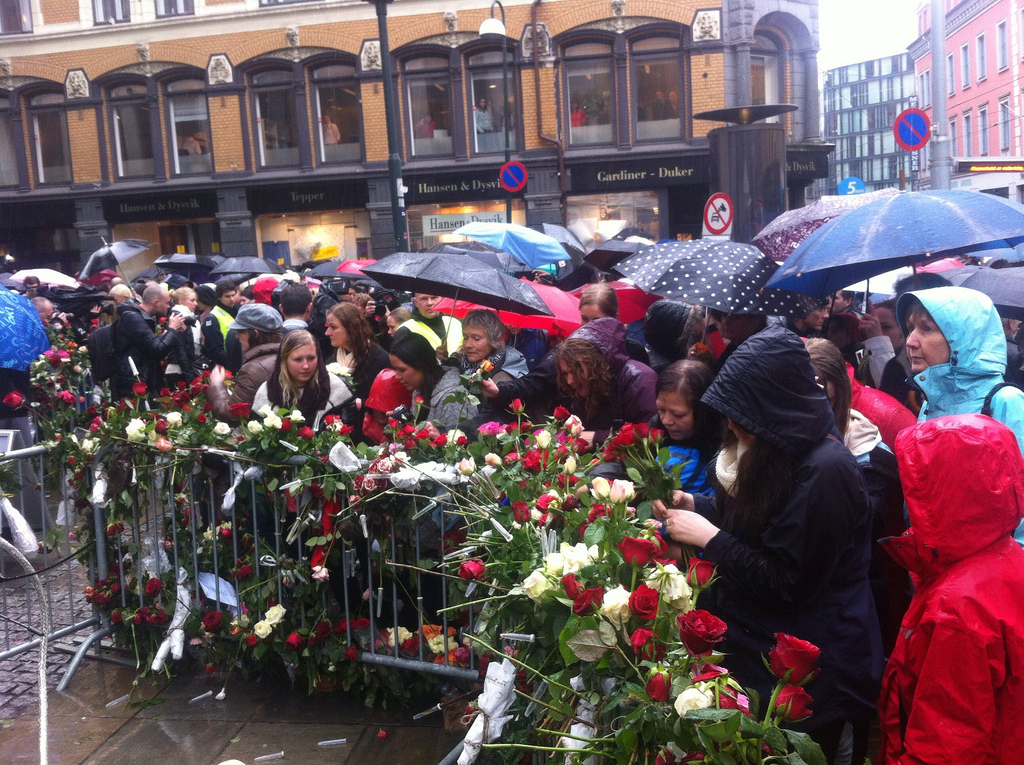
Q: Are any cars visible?
A: No, there are no cars.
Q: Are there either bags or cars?
A: No, there are no cars or bags.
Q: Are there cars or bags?
A: No, there are no cars or bags.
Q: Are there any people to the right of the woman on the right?
A: Yes, there is a person to the right of the woman.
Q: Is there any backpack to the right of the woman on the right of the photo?
A: No, there is a person to the right of the woman.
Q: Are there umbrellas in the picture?
A: Yes, there is an umbrella.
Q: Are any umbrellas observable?
A: Yes, there is an umbrella.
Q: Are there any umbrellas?
A: Yes, there is an umbrella.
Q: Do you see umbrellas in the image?
A: Yes, there is an umbrella.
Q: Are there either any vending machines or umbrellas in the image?
A: Yes, there is an umbrella.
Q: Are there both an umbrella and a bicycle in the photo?
A: No, there is an umbrella but no bicycles.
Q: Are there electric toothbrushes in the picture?
A: No, there are no electric toothbrushes.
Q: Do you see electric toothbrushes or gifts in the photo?
A: No, there are no electric toothbrushes or gifts.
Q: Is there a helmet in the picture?
A: No, there are no helmets.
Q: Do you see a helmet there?
A: No, there are no helmets.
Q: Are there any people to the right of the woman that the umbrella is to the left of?
A: Yes, there is a person to the right of the woman.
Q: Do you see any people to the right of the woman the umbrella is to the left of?
A: Yes, there is a person to the right of the woman.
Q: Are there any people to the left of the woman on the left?
A: No, the person is to the right of the woman.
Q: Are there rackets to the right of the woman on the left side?
A: No, there is a person to the right of the woman.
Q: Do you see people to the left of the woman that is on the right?
A: Yes, there is a person to the left of the woman.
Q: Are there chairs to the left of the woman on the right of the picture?
A: No, there is a person to the left of the woman.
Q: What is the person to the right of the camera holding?
A: The person is holding the umbrella.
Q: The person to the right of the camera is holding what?
A: The person is holding the umbrella.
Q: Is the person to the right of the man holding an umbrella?
A: Yes, the person is holding an umbrella.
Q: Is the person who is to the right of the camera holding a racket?
A: No, the person is holding an umbrella.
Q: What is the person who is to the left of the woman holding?
A: The person is holding the umbrella.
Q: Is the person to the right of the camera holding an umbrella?
A: Yes, the person is holding an umbrella.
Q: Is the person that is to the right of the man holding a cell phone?
A: No, the person is holding an umbrella.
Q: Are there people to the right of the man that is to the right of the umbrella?
A: Yes, there is a person to the right of the man.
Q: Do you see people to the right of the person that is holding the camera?
A: Yes, there is a person to the right of the man.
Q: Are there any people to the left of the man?
A: No, the person is to the right of the man.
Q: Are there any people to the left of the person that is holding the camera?
A: No, the person is to the right of the man.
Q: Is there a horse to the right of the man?
A: No, there is a person to the right of the man.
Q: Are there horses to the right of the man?
A: No, there is a person to the right of the man.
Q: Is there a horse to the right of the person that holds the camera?
A: No, there is a person to the right of the man.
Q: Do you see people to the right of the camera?
A: Yes, there is a person to the right of the camera.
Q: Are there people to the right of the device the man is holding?
A: Yes, there is a person to the right of the camera.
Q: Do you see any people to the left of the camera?
A: No, the person is to the right of the camera.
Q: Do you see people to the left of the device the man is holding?
A: No, the person is to the right of the camera.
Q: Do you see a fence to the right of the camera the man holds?
A: No, there is a person to the right of the camera.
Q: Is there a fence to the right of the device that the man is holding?
A: No, there is a person to the right of the camera.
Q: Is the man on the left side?
A: Yes, the man is on the left of the image.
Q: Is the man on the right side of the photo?
A: No, the man is on the left of the image.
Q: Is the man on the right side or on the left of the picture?
A: The man is on the left of the image.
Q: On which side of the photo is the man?
A: The man is on the left of the image.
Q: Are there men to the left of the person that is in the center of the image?
A: Yes, there is a man to the left of the person.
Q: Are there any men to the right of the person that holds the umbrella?
A: No, the man is to the left of the person.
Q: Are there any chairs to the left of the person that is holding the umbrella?
A: No, there is a man to the left of the person.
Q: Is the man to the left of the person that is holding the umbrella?
A: Yes, the man is to the left of the person.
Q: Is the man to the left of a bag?
A: No, the man is to the left of the person.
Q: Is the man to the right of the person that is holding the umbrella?
A: No, the man is to the left of the person.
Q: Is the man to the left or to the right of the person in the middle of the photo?
A: The man is to the left of the person.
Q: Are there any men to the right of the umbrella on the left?
A: Yes, there is a man to the right of the umbrella.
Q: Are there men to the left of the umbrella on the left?
A: No, the man is to the right of the umbrella.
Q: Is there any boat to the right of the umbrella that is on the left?
A: No, there is a man to the right of the umbrella.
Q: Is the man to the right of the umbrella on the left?
A: Yes, the man is to the right of the umbrella.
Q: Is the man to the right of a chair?
A: No, the man is to the right of the umbrella.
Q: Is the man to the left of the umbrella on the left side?
A: No, the man is to the right of the umbrella.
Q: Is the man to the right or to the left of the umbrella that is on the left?
A: The man is to the right of the umbrella.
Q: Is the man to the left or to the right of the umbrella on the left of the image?
A: The man is to the right of the umbrella.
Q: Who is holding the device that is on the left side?
A: The man is holding the camera.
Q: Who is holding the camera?
A: The man is holding the camera.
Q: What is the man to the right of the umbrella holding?
A: The man is holding the camera.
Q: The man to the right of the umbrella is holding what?
A: The man is holding the camera.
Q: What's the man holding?
A: The man is holding the camera.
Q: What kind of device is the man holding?
A: The man is holding the camera.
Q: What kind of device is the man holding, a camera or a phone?
A: The man is holding a camera.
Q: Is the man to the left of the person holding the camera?
A: Yes, the man is holding the camera.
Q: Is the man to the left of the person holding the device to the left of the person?
A: Yes, the man is holding the camera.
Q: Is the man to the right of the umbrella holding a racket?
A: No, the man is holding the camera.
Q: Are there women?
A: Yes, there is a woman.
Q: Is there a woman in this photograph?
A: Yes, there is a woman.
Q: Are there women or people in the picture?
A: Yes, there is a woman.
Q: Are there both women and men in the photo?
A: Yes, there are both a woman and a man.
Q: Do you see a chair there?
A: No, there are no chairs.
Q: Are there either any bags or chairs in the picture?
A: No, there are no chairs or bags.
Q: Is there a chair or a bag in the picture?
A: No, there are no chairs or bags.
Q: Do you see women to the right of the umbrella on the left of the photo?
A: Yes, there is a woman to the right of the umbrella.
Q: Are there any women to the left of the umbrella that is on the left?
A: No, the woman is to the right of the umbrella.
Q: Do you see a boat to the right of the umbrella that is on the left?
A: No, there is a woman to the right of the umbrella.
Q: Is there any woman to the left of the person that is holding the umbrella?
A: Yes, there is a woman to the left of the person.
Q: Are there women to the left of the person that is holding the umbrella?
A: Yes, there is a woman to the left of the person.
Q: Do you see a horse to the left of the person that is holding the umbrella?
A: No, there is a woman to the left of the person.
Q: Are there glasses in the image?
A: No, there are no glasses.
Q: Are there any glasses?
A: No, there are no glasses.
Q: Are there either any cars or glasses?
A: No, there are no glasses or cars.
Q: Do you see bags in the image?
A: No, there are no bags.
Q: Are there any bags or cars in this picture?
A: No, there are no bags or cars.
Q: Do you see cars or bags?
A: No, there are no bags or cars.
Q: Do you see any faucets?
A: No, there are no faucets.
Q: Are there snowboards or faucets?
A: No, there are no faucets or snowboards.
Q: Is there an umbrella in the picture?
A: Yes, there is an umbrella.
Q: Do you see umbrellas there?
A: Yes, there is an umbrella.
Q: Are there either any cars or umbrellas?
A: Yes, there is an umbrella.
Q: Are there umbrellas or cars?
A: Yes, there is an umbrella.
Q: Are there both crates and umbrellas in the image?
A: No, there is an umbrella but no crates.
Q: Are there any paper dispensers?
A: No, there are no paper dispensers.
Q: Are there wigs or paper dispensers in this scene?
A: No, there are no paper dispensers or wigs.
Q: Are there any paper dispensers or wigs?
A: No, there are no paper dispensers or wigs.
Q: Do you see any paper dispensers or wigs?
A: No, there are no paper dispensers or wigs.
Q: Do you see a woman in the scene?
A: Yes, there is a woman.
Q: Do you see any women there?
A: Yes, there is a woman.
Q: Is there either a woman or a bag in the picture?
A: Yes, there is a woman.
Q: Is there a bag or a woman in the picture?
A: Yes, there is a woman.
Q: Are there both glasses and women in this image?
A: No, there is a woman but no glasses.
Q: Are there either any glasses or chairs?
A: No, there are no glasses or chairs.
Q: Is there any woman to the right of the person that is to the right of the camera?
A: Yes, there is a woman to the right of the person.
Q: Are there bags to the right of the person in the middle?
A: No, there is a woman to the right of the person.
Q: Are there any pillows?
A: No, there are no pillows.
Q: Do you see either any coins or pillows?
A: No, there are no pillows or coins.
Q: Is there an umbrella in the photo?
A: Yes, there is an umbrella.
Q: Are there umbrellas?
A: Yes, there is an umbrella.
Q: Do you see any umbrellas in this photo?
A: Yes, there is an umbrella.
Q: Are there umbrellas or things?
A: Yes, there is an umbrella.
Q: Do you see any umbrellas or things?
A: Yes, there is an umbrella.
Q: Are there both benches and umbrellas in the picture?
A: No, there is an umbrella but no benches.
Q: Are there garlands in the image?
A: No, there are no garlands.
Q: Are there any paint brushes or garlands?
A: No, there are no garlands or paint brushes.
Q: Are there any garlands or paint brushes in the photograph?
A: No, there are no garlands or paint brushes.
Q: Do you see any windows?
A: Yes, there is a window.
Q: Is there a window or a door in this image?
A: Yes, there is a window.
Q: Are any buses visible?
A: No, there are no buses.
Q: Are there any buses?
A: No, there are no buses.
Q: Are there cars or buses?
A: No, there are no buses or cars.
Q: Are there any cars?
A: No, there are no cars.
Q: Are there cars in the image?
A: No, there are no cars.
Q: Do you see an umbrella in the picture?
A: Yes, there is an umbrella.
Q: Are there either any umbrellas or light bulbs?
A: Yes, there is an umbrella.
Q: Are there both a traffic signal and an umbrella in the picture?
A: No, there is an umbrella but no traffic lights.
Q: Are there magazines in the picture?
A: No, there are no magazines.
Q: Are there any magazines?
A: No, there are no magazines.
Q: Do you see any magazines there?
A: No, there are no magazines.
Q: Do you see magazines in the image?
A: No, there are no magazines.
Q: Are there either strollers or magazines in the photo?
A: No, there are no magazines or strollers.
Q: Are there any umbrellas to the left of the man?
A: Yes, there is an umbrella to the left of the man.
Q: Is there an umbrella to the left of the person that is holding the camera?
A: Yes, there is an umbrella to the left of the man.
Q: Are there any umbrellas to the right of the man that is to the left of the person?
A: No, the umbrella is to the left of the man.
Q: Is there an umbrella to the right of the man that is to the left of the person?
A: No, the umbrella is to the left of the man.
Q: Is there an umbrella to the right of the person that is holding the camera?
A: No, the umbrella is to the left of the man.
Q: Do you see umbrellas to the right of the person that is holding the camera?
A: No, the umbrella is to the left of the man.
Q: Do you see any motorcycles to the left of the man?
A: No, there is an umbrella to the left of the man.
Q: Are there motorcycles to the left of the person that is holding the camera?
A: No, there is an umbrella to the left of the man.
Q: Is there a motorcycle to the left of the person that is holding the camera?
A: No, there is an umbrella to the left of the man.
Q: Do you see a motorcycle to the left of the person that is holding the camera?
A: No, there is an umbrella to the left of the man.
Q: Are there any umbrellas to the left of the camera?
A: Yes, there is an umbrella to the left of the camera.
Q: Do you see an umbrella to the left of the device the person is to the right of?
A: Yes, there is an umbrella to the left of the camera.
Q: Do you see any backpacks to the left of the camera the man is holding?
A: No, there is an umbrella to the left of the camera.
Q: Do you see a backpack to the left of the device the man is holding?
A: No, there is an umbrella to the left of the camera.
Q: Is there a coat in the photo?
A: Yes, there is a coat.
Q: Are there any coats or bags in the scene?
A: Yes, there is a coat.